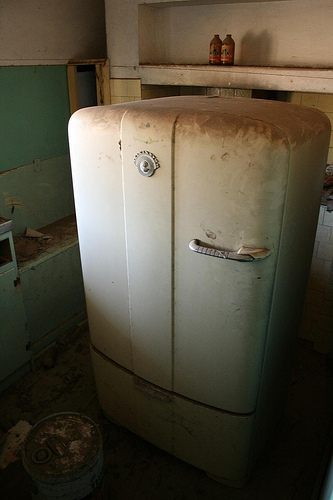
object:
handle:
[187, 238, 271, 263]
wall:
[2, 63, 63, 154]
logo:
[133, 150, 160, 178]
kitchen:
[0, 0, 331, 500]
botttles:
[209, 33, 236, 66]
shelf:
[136, 62, 333, 95]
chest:
[66, 94, 333, 491]